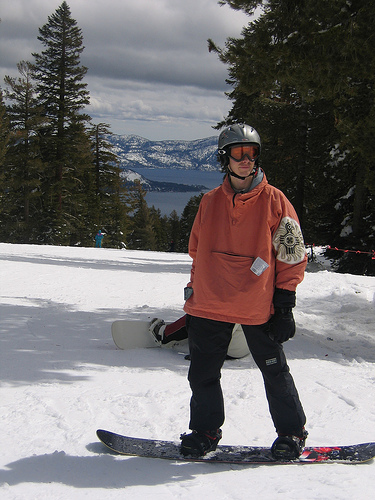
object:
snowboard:
[94, 423, 372, 466]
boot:
[270, 426, 306, 460]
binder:
[272, 432, 304, 446]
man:
[179, 122, 321, 459]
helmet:
[218, 123, 264, 151]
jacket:
[182, 183, 307, 326]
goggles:
[226, 140, 259, 163]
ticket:
[250, 254, 273, 278]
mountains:
[98, 122, 232, 174]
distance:
[8, 11, 363, 211]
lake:
[129, 164, 230, 219]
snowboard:
[111, 315, 167, 353]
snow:
[4, 239, 373, 499]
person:
[179, 122, 308, 462]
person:
[94, 224, 107, 249]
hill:
[4, 228, 373, 499]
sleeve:
[267, 190, 315, 310]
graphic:
[270, 216, 308, 267]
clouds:
[3, 5, 245, 127]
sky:
[2, 0, 219, 132]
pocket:
[211, 246, 263, 297]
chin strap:
[228, 168, 257, 180]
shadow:
[5, 447, 242, 498]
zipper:
[215, 248, 254, 259]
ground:
[3, 240, 374, 499]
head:
[217, 123, 261, 178]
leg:
[243, 310, 321, 441]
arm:
[267, 192, 309, 343]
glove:
[272, 286, 297, 343]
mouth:
[237, 166, 252, 171]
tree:
[34, 6, 88, 250]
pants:
[184, 314, 309, 440]